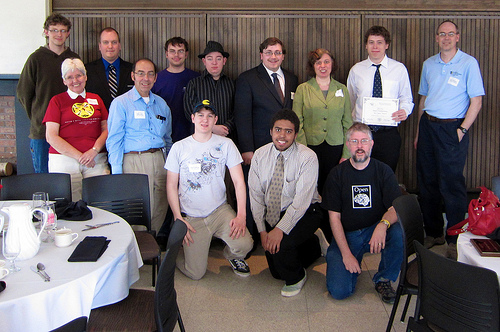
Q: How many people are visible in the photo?
A: Thirteen.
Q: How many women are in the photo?
A: Two.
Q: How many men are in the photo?
A: Eleven.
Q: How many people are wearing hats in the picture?
A: Two.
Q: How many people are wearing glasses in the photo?
A: Six.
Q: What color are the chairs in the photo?
A: Black.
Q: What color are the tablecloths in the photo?
A: White.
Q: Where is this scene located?
A: In a meeting room.